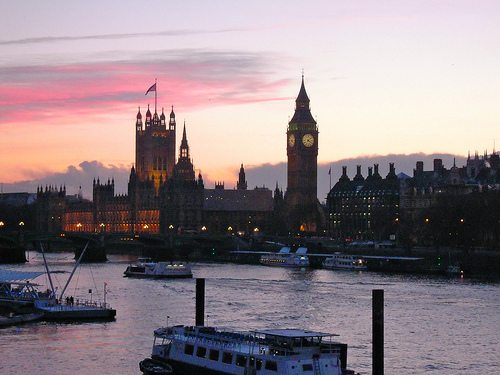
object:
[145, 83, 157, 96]
flag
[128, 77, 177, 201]
building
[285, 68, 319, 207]
tower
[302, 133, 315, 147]
clock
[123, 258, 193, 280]
boat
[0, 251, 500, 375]
river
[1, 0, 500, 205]
sky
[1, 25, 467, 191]
clouds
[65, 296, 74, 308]
people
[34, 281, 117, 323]
boat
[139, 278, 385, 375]
boat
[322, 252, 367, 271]
boat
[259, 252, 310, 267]
boat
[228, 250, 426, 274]
pier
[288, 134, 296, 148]
clock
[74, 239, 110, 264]
support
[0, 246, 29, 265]
support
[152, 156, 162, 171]
window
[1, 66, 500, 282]
town